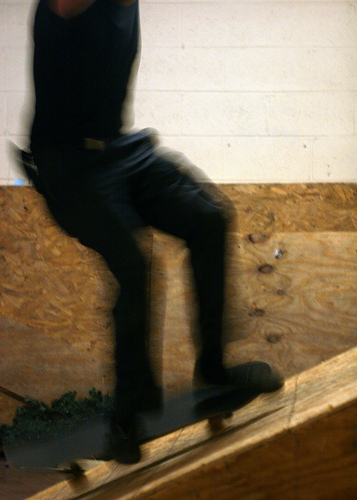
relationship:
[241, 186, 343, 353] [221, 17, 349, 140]
wood against wall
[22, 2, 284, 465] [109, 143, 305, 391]
man wearing sneakers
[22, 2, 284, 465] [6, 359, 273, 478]
man riding skateboard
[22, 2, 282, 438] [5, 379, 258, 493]
man standing on skateboard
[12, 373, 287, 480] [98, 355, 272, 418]
skateboard on feet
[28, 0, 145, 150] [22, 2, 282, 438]
shirt on man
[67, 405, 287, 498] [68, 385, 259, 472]
shadow of board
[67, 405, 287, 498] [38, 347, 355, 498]
shadow on ramp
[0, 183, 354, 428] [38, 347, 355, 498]
wall on side of ramp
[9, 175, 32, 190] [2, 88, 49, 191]
sticker on wall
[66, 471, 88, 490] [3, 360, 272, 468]
wheel of skateboard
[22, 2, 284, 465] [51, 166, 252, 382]
man wearing jeans